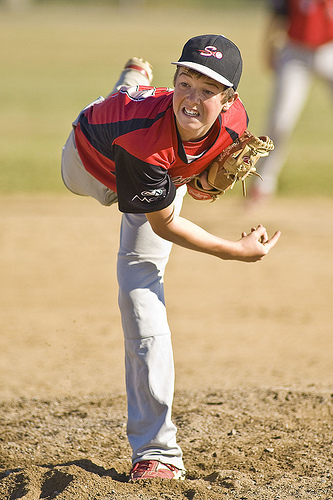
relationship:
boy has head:
[62, 34, 286, 482] [171, 36, 243, 135]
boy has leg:
[62, 34, 286, 482] [116, 202, 189, 483]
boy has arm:
[62, 34, 286, 482] [116, 145, 283, 263]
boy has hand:
[62, 34, 286, 482] [236, 222, 283, 265]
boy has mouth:
[62, 34, 286, 482] [177, 106, 206, 121]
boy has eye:
[62, 34, 286, 482] [180, 81, 191, 92]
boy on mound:
[62, 34, 286, 482] [0, 391, 332, 500]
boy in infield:
[60, 34, 286, 481] [1, 1, 331, 399]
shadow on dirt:
[0, 458, 129, 499] [1, 438, 331, 498]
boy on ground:
[60, 34, 286, 481] [0, 195, 331, 498]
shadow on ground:
[0, 458, 129, 499] [0, 195, 331, 498]